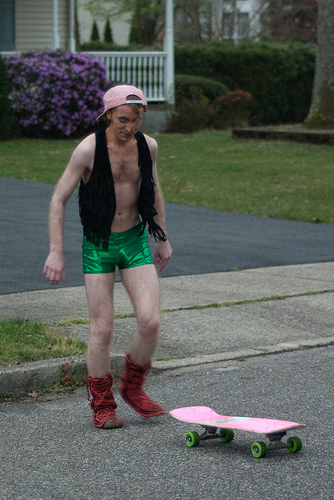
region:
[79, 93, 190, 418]
this is a man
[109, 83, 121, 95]
this is a ca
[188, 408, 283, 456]
this is a skate board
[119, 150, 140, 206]
the man is light skinned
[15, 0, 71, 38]
this is a wall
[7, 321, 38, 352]
this is a grass area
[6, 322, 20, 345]
the grass is green in color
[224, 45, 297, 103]
this is a fence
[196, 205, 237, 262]
this is a road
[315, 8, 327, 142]
this is a tree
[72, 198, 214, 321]
man is wearing gold short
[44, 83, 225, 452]
man is wearing gold short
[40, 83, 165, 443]
this is a man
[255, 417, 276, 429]
the skate board is pink in color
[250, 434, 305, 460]
the wheels are green in color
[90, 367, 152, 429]
the shoes are red in color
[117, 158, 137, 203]
the man is bare chested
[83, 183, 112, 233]
the coat is black in color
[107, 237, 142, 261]
the pant is green in color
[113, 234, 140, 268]
the pant is short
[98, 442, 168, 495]
the road is tarmacked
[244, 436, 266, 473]
part of a wheel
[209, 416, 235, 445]
edge of a skateboard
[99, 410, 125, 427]
edge of a shoe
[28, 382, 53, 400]
part of an edge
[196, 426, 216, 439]
part of a wheel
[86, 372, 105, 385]
edge of a shoe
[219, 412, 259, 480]
part of a skateboard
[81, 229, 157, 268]
The green shorts the man is wearing.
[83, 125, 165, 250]
The black frilly vest the man is wearing.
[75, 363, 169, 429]
The red boots the man is wearing.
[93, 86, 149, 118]
The pink hat the man has on.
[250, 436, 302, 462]
The front wheels of the skateboard.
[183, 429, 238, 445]
The back wheels of the skateboard.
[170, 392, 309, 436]
The skateboard attached to the green wheels.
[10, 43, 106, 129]
The bush of purple flowers in front of the house.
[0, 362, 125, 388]
The curb behind the man.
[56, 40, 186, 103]
The white porch of the house behind the man.